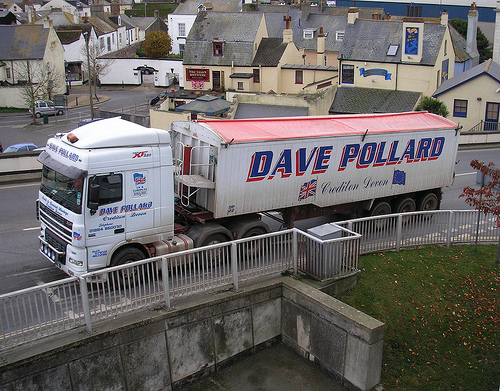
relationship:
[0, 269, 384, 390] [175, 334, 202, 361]
wall made of cement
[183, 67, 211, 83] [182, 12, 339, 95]
sign on building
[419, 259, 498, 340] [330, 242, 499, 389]
leaves are on grass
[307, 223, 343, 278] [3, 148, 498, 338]
box beside street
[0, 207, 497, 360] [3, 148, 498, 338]
fence beside street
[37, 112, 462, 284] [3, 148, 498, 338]
truck on street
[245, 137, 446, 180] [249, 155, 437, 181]
writing has red trim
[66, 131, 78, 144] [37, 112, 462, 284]
light on top of truck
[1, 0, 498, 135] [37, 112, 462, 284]
houses are behind truck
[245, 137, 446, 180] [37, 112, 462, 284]
logo on a truck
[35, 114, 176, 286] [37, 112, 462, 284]
cab in front of truck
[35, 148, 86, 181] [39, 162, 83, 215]
visor on window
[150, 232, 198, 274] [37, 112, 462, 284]
tank on truck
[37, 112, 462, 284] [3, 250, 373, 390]
truck going over bridge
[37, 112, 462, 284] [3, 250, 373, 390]
truck driving over bridge